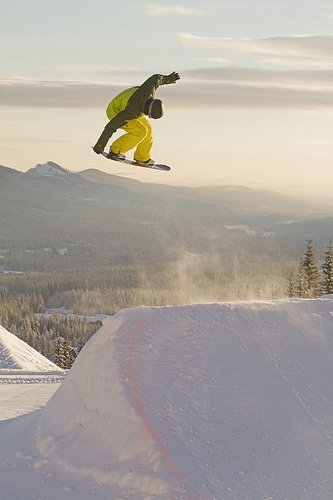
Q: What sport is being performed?
A: Snowboarding.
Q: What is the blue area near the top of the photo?
A: The sky.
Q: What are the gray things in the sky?
A: Clouds.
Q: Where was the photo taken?
A: At a ski slope.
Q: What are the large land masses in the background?
A: Mountains.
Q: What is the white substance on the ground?
A: Snow.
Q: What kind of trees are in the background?
A: Pine trees.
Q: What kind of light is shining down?
A: Sunlight.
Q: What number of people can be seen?
A: One.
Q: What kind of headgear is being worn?
A: A helmet.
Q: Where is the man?
A: In the air.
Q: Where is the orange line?
A: In the snow.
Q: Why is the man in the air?
A: He's doing a trick.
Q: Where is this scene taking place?
A: Mountains.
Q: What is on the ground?
A: Snow.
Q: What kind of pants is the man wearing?
A: Ski pants.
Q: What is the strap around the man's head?
A: Goggles.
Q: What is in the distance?
A: The mountains.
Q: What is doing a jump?
A: The snowboarder.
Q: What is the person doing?
A: Snowboarding.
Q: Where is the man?
A: In the air.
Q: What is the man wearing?
A: Yellow snowsuit.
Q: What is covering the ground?
A: Snow.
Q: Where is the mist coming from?
A: The snow.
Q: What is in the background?
A: Mountains.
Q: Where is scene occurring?
A: Ski slope.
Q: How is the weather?
A: Clear and cold.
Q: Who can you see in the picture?
A: A male snowboarder.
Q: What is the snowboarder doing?
A: Making a jump.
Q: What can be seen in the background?
A: Mountain.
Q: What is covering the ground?
A: Snow.